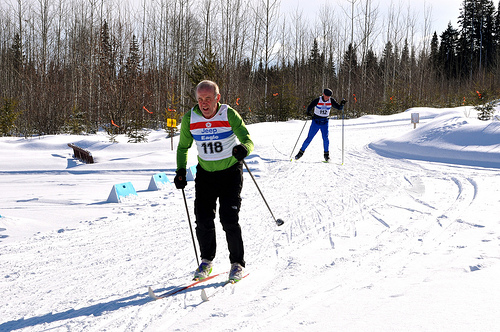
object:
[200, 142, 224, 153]
number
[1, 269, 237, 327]
shadow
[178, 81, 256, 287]
person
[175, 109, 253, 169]
sweater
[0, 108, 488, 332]
trail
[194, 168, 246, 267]
pants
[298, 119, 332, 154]
pants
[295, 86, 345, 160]
person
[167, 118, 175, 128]
sign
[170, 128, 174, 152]
pole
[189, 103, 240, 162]
vest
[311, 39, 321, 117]
tree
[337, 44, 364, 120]
tree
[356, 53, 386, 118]
tree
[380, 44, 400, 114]
tree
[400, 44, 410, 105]
tree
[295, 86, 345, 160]
skiier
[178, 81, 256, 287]
skiier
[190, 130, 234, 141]
stripe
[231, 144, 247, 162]
glove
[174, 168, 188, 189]
glove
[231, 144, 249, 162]
hand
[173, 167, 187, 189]
hand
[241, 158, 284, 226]
skiing pole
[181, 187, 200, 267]
skiing pole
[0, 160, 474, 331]
tracks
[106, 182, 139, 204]
trail marker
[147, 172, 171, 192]
trail marker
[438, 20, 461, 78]
tree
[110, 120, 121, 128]
flag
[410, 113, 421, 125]
sign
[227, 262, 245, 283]
shoe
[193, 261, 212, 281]
shoe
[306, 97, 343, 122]
sweater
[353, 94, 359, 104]
flag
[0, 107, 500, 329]
ground